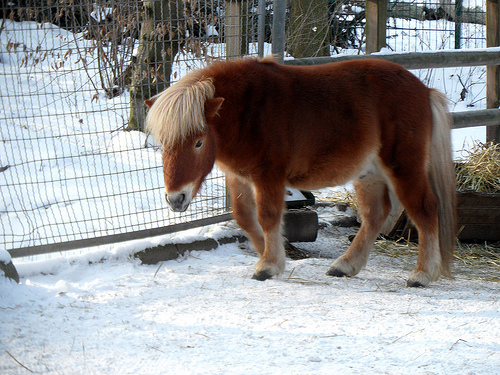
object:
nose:
[162, 190, 189, 210]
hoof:
[249, 264, 279, 278]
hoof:
[326, 262, 352, 277]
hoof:
[403, 277, 428, 289]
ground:
[0, 21, 499, 374]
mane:
[139, 73, 219, 146]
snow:
[0, 19, 500, 373]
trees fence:
[90, 16, 160, 114]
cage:
[0, 0, 285, 261]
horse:
[142, 55, 467, 290]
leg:
[391, 162, 444, 269]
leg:
[333, 172, 390, 262]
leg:
[257, 177, 286, 263]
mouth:
[165, 202, 190, 215]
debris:
[312, 329, 344, 344]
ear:
[204, 96, 229, 117]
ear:
[140, 98, 158, 112]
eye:
[192, 137, 208, 150]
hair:
[143, 74, 212, 150]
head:
[142, 81, 225, 215]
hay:
[452, 139, 500, 192]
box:
[373, 162, 500, 243]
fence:
[0, 0, 500, 261]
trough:
[454, 160, 499, 239]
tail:
[423, 88, 460, 283]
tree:
[91, 1, 201, 135]